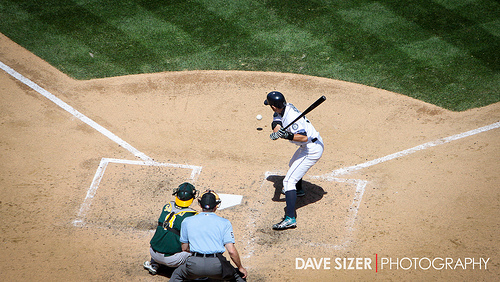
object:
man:
[266, 91, 325, 229]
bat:
[272, 95, 327, 140]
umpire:
[166, 190, 249, 282]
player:
[143, 182, 198, 276]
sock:
[285, 189, 297, 218]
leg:
[272, 143, 324, 230]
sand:
[0, 30, 500, 281]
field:
[0, 0, 499, 282]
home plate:
[216, 193, 243, 211]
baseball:
[256, 114, 263, 120]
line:
[0, 61, 152, 162]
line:
[319, 121, 499, 178]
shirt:
[179, 212, 236, 254]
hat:
[172, 182, 200, 207]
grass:
[0, 0, 499, 112]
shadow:
[257, 128, 263, 131]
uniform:
[140, 182, 199, 277]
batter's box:
[71, 156, 368, 249]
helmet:
[264, 91, 286, 109]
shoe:
[272, 215, 297, 229]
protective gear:
[198, 189, 221, 212]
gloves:
[270, 127, 294, 141]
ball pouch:
[217, 253, 237, 280]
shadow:
[266, 175, 327, 218]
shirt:
[150, 203, 195, 257]